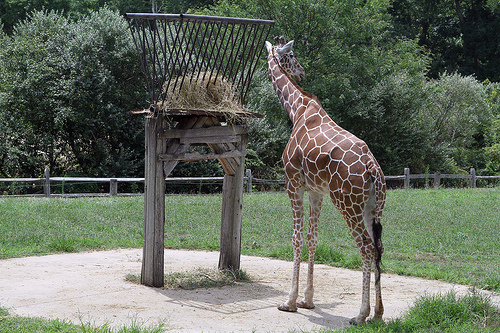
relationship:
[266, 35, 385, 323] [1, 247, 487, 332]
giraffe on concrete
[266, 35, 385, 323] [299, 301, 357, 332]
giraffe has shadow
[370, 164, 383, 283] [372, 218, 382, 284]
tail has hair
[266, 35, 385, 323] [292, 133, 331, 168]
giraffe has spots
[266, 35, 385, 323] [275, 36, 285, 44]
giraffe has horns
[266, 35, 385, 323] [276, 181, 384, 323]
giraffe has legs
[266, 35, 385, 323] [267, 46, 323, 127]
giraffe has neck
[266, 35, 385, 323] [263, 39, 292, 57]
giraffe has ears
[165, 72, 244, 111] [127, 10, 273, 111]
hay in manger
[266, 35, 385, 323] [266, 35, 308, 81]
giraffe has a head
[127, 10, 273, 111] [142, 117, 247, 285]
manger on stand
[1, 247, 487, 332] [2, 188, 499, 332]
concrete in grass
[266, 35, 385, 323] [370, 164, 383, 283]
giraffe has tail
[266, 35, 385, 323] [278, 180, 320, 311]
giraffe has front legs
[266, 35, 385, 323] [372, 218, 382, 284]
giraffe has hair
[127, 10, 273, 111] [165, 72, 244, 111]
manger has hay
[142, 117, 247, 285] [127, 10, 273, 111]
stand for manger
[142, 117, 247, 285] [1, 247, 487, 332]
stand on concrete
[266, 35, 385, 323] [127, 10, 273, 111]
giraffe near manger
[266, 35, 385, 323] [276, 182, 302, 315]
giraffe has left front leg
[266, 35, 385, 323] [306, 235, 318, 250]
giraffe has knee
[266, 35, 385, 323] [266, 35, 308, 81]
giraffe has head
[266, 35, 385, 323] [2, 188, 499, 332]
giraffe facing grass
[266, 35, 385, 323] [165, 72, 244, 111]
giraffe eating hay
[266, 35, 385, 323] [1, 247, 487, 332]
giraffe standing on concrete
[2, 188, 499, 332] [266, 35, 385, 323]
grass behind giraffe